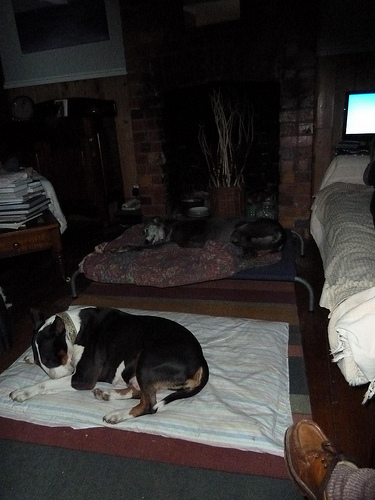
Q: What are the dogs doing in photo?
A: Laying down.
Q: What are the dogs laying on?
A: Blankets.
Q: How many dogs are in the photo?
A: Two.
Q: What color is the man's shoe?
A: Brown.